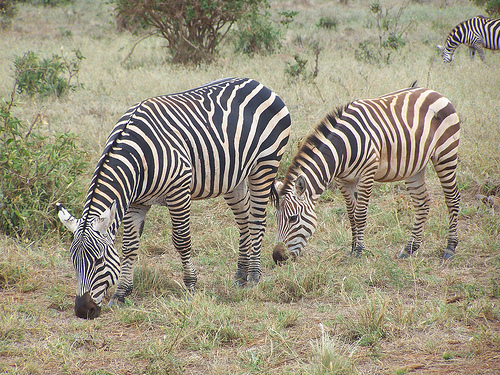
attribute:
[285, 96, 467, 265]
zebra — grazing, standing, black, white, striped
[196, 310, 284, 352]
grass — long, green, yellow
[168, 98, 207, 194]
stripes — black